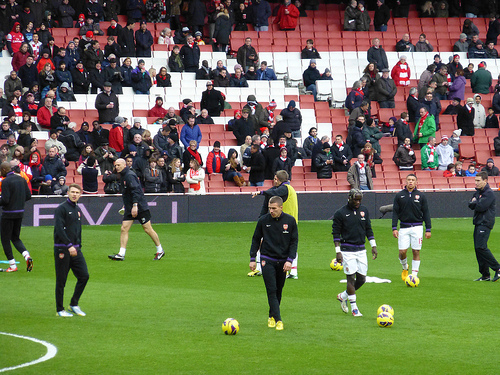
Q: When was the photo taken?
A: During the day.